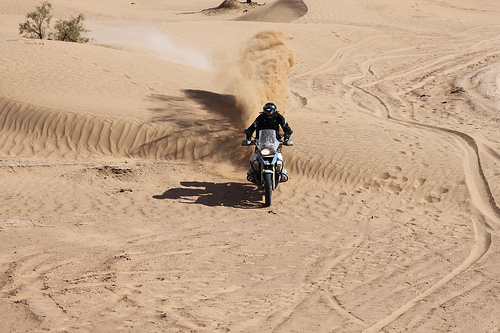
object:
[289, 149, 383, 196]
sand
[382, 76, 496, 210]
tire tracks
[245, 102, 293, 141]
biker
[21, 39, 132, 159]
sand dune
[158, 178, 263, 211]
shadow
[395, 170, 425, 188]
foot prints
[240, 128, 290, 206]
bike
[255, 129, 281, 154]
windshield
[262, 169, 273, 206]
front tire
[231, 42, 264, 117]
sand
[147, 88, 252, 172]
shadow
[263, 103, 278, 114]
helmet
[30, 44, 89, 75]
sand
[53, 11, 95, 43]
trees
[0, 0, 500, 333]
desert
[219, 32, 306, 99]
cloud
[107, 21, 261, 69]
smoke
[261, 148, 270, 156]
headlight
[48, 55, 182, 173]
dunes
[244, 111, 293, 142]
jacket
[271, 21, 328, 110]
dirt